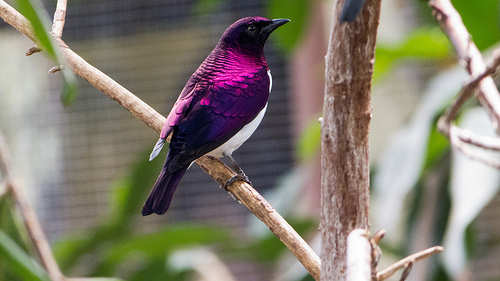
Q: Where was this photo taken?
A: Outside in the woods.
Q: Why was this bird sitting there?
A: Relaxing.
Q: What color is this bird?
A: Purple and white.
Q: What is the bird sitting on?
A: Branch.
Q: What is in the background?
A: A house.